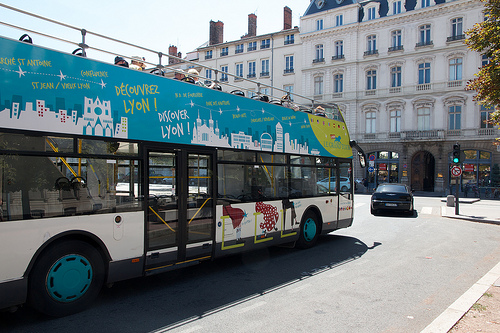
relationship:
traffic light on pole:
[448, 138, 460, 171] [456, 183, 463, 214]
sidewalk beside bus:
[428, 195, 500, 234] [25, 26, 347, 286]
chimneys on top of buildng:
[202, 13, 299, 35] [216, 6, 499, 146]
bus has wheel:
[25, 26, 347, 286] [30, 239, 114, 317]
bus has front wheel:
[25, 26, 347, 286] [294, 204, 325, 249]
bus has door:
[25, 26, 347, 286] [143, 153, 214, 268]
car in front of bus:
[370, 168, 418, 223] [25, 26, 347, 286]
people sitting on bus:
[125, 61, 245, 93] [25, 26, 347, 286]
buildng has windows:
[216, 6, 499, 146] [298, 32, 435, 57]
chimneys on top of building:
[202, 13, 299, 35] [210, 21, 499, 185]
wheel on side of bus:
[30, 239, 114, 317] [25, 26, 347, 286]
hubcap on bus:
[47, 258, 95, 305] [25, 26, 347, 286]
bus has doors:
[25, 26, 347, 286] [128, 143, 232, 258]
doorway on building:
[401, 144, 437, 202] [210, 21, 499, 185]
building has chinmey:
[210, 21, 499, 185] [244, 10, 263, 43]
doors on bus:
[128, 143, 232, 258] [25, 26, 347, 286]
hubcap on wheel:
[47, 258, 95, 305] [30, 239, 114, 317]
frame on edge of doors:
[138, 139, 218, 162] [128, 143, 232, 258]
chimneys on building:
[202, 13, 299, 35] [210, 21, 499, 185]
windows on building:
[298, 32, 435, 57] [210, 21, 499, 185]